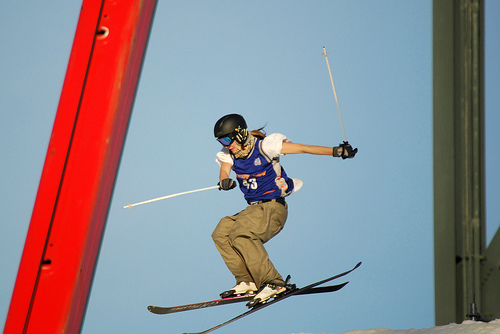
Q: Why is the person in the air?
A: Skiing.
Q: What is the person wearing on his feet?
A: Skis.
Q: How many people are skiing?
A: One.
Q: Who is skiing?
A: A man.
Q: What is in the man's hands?
A: Poles.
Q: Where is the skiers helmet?
A: On his head.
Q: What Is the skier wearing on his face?
A: Goggles.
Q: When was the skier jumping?
A: Daytime.